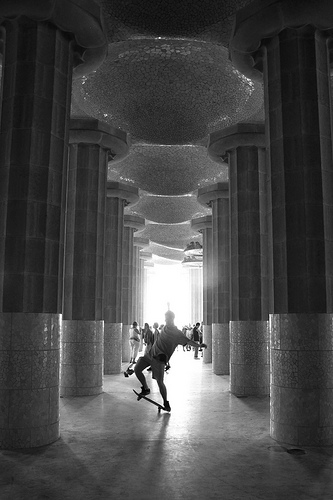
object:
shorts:
[134, 352, 165, 379]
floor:
[2, 340, 327, 500]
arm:
[176, 329, 207, 349]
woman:
[129, 321, 142, 363]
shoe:
[163, 399, 171, 412]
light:
[125, 254, 205, 441]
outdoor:
[144, 249, 192, 331]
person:
[193, 322, 200, 359]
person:
[141, 323, 154, 345]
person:
[153, 322, 161, 336]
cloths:
[129, 327, 140, 358]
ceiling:
[49, 2, 264, 267]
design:
[72, 34, 265, 147]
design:
[107, 143, 230, 195]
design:
[124, 195, 213, 224]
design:
[134, 222, 202, 250]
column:
[0, 16, 74, 458]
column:
[60, 128, 108, 397]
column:
[103, 194, 123, 374]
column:
[263, 17, 332, 443]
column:
[229, 145, 268, 396]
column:
[212, 199, 229, 374]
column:
[203, 221, 213, 364]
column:
[122, 226, 133, 361]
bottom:
[0, 311, 63, 449]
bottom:
[61, 320, 103, 398]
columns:
[190, 21, 332, 446]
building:
[1, 1, 332, 500]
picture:
[0, 0, 333, 500]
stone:
[281, 100, 300, 132]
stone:
[12, 61, 31, 94]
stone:
[235, 189, 245, 210]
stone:
[216, 215, 228, 232]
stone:
[25, 238, 42, 273]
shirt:
[149, 325, 190, 364]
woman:
[192, 322, 202, 359]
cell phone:
[132, 388, 170, 413]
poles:
[201, 24, 332, 467]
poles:
[0, 18, 145, 451]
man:
[135, 309, 208, 413]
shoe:
[137, 386, 150, 401]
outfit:
[129, 327, 141, 359]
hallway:
[0, 350, 333, 500]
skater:
[134, 309, 208, 411]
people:
[129, 310, 207, 409]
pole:
[62, 143, 104, 394]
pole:
[229, 144, 272, 395]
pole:
[101, 197, 120, 373]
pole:
[121, 225, 136, 362]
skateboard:
[133, 389, 170, 413]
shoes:
[137, 386, 171, 412]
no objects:
[267, 442, 307, 461]